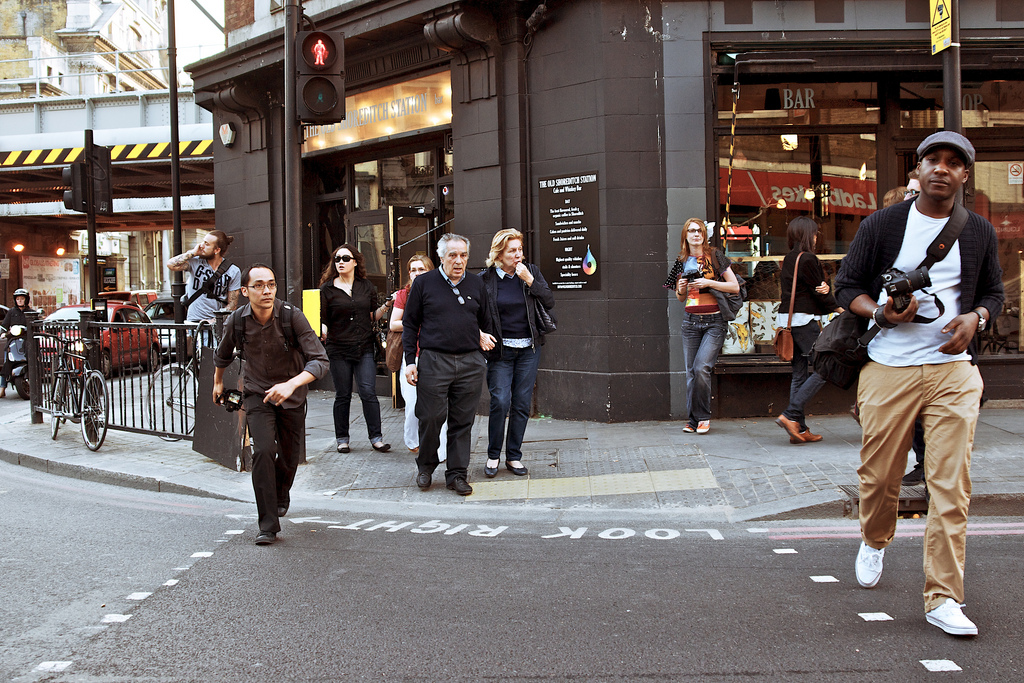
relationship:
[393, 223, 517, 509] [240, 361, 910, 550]
person on sidewalk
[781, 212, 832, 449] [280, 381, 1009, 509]
person on sidewalk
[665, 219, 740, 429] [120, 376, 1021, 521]
person on sidewalk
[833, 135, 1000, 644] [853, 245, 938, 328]
man holding camera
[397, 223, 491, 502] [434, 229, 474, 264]
man has gray hair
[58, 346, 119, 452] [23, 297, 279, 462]
bike leans on rail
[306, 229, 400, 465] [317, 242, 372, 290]
woman has long hair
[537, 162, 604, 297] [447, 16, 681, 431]
sign on wall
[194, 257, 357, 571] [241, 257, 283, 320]
person has head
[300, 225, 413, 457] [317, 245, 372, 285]
person has head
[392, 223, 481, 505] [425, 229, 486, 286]
person has head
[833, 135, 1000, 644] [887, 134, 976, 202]
man has head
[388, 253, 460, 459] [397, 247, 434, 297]
person has head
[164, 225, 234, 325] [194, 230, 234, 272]
person has head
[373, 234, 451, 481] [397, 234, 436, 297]
person has head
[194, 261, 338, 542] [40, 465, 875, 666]
person on street corner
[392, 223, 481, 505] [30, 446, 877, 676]
person on street corner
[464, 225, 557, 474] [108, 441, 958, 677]
person on street corner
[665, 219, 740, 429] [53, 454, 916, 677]
person on street corner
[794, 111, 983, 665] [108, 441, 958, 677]
person on street corner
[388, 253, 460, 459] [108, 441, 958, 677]
person on street corner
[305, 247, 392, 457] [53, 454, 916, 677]
person on street corner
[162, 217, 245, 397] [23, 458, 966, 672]
person on street corner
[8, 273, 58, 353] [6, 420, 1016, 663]
person on street corner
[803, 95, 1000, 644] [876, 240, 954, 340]
man holding camera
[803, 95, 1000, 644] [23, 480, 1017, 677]
man crosses street